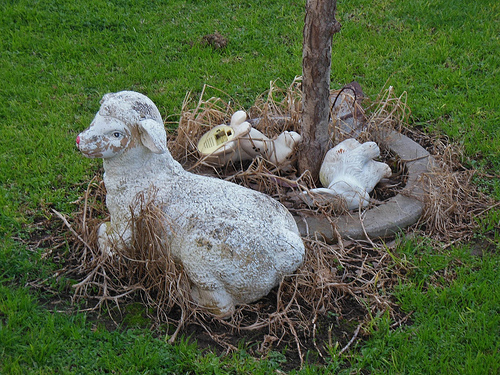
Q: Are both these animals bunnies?
A: Yes, all the animals are bunnies.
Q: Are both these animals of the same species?
A: Yes, all the animals are bunnies.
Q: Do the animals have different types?
A: No, all the animals are bunnies.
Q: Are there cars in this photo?
A: No, there are no cars.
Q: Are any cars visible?
A: No, there are no cars.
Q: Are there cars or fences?
A: No, there are no cars or fences.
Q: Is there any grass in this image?
A: Yes, there is grass.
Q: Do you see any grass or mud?
A: Yes, there is grass.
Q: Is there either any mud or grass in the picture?
A: Yes, there is grass.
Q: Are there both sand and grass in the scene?
A: No, there is grass but no sand.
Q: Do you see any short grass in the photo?
A: Yes, there is short grass.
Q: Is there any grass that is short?
A: Yes, there is grass that is short.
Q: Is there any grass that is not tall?
A: Yes, there is short grass.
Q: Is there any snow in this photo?
A: No, there is no snow.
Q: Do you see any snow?
A: No, there is no snow.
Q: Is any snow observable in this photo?
A: No, there is no snow.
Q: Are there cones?
A: No, there are no cones.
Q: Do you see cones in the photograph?
A: No, there are no cones.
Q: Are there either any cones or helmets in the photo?
A: No, there are no cones or helmets.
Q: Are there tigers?
A: No, there are no tigers.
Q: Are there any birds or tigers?
A: No, there are no tigers or birds.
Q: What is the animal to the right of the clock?
A: The animal is a bunny.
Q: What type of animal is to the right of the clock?
A: The animal is a bunny.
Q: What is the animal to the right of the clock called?
A: The animal is a bunny.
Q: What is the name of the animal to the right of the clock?
A: The animal is a bunny.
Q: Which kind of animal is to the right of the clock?
A: The animal is a bunny.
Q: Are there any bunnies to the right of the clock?
A: Yes, there is a bunny to the right of the clock.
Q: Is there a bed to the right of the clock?
A: No, there is a bunny to the right of the clock.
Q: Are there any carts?
A: No, there are no carts.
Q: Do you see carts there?
A: No, there are no carts.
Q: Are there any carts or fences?
A: No, there are no carts or fences.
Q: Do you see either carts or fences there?
A: No, there are no carts or fences.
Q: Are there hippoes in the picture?
A: No, there are no hippoes.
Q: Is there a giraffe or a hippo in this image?
A: No, there are no hippoes or giraffes.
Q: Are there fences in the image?
A: No, there are no fences.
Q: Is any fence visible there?
A: No, there are no fences.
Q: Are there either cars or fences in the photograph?
A: No, there are no fences or cars.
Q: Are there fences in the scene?
A: No, there are no fences.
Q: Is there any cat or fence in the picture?
A: No, there are no fences or cats.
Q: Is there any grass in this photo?
A: Yes, there is grass.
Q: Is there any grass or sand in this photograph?
A: Yes, there is grass.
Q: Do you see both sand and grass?
A: No, there is grass but no sand.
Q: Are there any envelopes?
A: No, there are no envelopes.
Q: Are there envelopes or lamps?
A: No, there are no envelopes or lamps.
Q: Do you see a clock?
A: Yes, there is a clock.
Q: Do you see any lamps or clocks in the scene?
A: Yes, there is a clock.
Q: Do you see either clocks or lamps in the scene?
A: Yes, there is a clock.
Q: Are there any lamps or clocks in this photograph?
A: Yes, there is a clock.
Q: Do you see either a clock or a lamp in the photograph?
A: Yes, there is a clock.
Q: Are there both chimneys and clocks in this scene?
A: No, there is a clock but no chimneys.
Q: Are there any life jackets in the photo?
A: No, there are no life jackets.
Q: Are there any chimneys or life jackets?
A: No, there are no life jackets or chimneys.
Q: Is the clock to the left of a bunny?
A: Yes, the clock is to the left of a bunny.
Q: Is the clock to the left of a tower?
A: No, the clock is to the left of a bunny.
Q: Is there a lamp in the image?
A: No, there are no lamps.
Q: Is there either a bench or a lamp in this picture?
A: No, there are no lamps or benches.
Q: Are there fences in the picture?
A: No, there are no fences.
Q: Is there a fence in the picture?
A: No, there are no fences.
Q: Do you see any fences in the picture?
A: No, there are no fences.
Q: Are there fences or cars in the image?
A: No, there are no fences or cars.